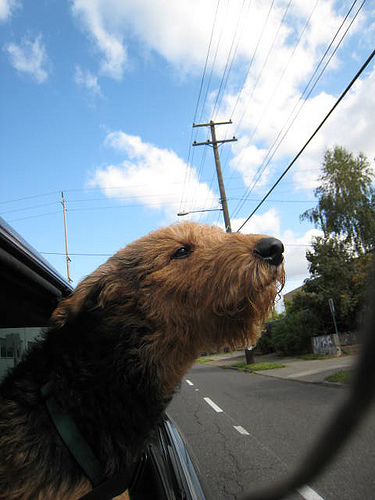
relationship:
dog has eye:
[0, 220, 285, 498] [171, 246, 190, 258]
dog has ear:
[0, 220, 285, 498] [53, 251, 166, 308]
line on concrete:
[183, 376, 196, 388] [163, 349, 371, 498]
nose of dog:
[252, 234, 286, 265] [0, 220, 285, 498]